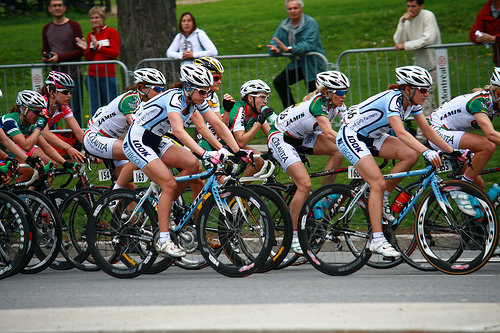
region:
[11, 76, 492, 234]
people riding bikes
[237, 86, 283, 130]
a person drinking a water bottle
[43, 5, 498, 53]
people standing behind the gate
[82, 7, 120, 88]
a person wearing a red shirt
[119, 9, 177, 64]
the trunk of the tree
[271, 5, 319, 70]
a person clapping their hands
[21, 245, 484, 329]
the street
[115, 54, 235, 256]
cyclist white unifrom wearing white helmet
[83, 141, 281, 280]
blue bicycle in race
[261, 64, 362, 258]
cyclist in white uniform wearing white helmet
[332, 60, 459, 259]
cyclist in white uniform wearing white helmet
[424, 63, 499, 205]
cyclist in white uniform wearing white helmet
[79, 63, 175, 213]
cyclist in white uniform wearing white helmet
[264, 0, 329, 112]
man watching in black pants and teal coat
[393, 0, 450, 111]
man wearing cream sweater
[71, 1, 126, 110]
woman wearing red sweater and blue jeans clapping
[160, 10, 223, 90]
woman watching in long sleeve shirt with black bag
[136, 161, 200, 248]
leg of a person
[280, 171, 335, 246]
leg of a person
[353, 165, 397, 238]
leg of a person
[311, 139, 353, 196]
leg of a person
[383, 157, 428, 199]
leg of a person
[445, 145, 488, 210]
leg of a person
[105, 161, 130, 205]
leg of a person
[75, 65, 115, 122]
leg of a person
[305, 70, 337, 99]
leg of a person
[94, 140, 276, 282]
this is a bike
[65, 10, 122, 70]
woman wearing a red shirt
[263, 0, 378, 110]
man is leaning on barrier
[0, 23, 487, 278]
a group of cyclist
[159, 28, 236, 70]
woman wearing a white shirt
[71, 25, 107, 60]
woman has hands up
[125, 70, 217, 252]
a woman on a bike in a race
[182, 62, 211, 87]
a helmet on a woman's head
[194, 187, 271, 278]
a tire on a bike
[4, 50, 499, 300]
a group of cyclist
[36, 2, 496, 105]
a group of spectators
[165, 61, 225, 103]
a white bike helmet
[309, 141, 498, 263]
a light blue bike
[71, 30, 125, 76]
a red and white shirt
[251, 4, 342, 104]
man leaning on a barrier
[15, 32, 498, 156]
a row of barriers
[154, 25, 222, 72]
woman wearing a white sweater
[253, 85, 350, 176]
a white and green uniform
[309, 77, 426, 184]
a white and blue uniform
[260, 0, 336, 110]
Man clapping in green coat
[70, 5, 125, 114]
Woman clapping in red shirt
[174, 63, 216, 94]
White and black bicycle helmet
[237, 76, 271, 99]
White and black bicycle helmet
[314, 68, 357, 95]
White and black bicycle helmet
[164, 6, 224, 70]
Woman standing in a white shirt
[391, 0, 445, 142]
Man standing in a cream shirt and khakis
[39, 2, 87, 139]
Man standing in a burgundy shirt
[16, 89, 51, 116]
White and black bicycle helmet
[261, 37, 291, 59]
Hands that are clapping together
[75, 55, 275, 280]
biker on the street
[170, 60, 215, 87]
silver colored helmet on biker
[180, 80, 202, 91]
black colored glasses on biker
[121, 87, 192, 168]
blue and white jersey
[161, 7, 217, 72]
woman wearing all white